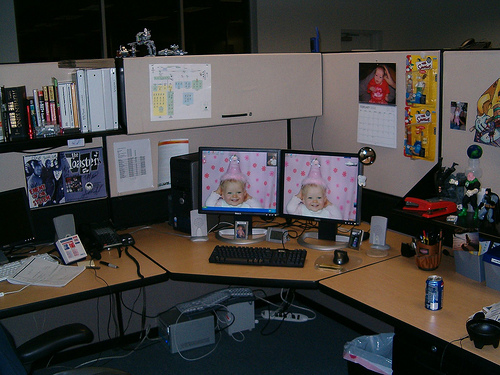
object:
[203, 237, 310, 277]
black keyboard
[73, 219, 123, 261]
telephone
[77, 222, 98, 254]
handset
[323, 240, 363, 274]
computer mouse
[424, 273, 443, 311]
can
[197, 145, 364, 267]
computer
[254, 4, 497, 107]
wall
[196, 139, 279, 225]
screen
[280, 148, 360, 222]
screen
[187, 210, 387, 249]
speakers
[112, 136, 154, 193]
list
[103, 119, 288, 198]
board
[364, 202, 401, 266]
computer speaker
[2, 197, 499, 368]
table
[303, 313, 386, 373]
trash can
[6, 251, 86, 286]
notebook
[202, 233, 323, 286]
keyboard desk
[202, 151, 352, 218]
pictures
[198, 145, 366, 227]
monitors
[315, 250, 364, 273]
pad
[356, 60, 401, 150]
calendar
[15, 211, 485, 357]
desk